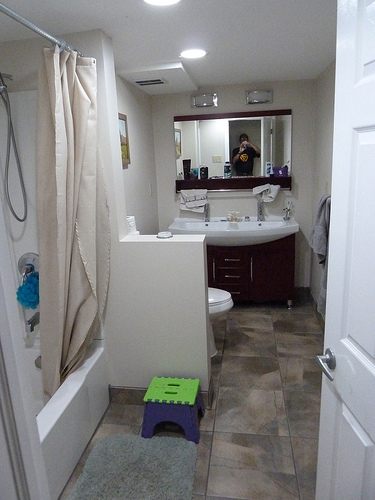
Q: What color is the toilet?
A: White.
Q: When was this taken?
A: Daytime.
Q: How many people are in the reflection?
A: 1.